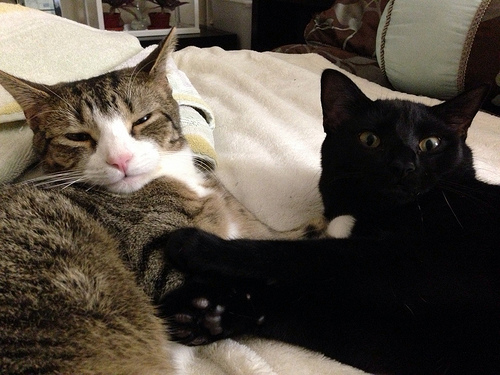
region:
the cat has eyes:
[348, 115, 445, 165]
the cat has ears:
[305, 51, 486, 130]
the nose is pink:
[97, 147, 142, 174]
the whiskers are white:
[37, 168, 92, 192]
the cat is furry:
[20, 240, 110, 320]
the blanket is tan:
[222, 67, 289, 173]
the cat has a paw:
[160, 294, 238, 346]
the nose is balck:
[388, 154, 418, 186]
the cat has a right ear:
[138, 20, 193, 76]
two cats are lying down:
[11, 42, 493, 358]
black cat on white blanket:
[140, 68, 497, 367]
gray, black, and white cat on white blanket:
[4, 29, 352, 371]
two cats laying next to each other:
[2, 27, 497, 370]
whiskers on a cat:
[15, 147, 221, 187]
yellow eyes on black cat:
[355, 125, 440, 155]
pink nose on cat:
[99, 146, 139, 174]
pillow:
[373, 1, 491, 101]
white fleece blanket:
[157, 43, 499, 373]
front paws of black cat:
[138, 225, 242, 357]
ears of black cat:
[313, 63, 486, 139]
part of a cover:
[266, 148, 278, 160]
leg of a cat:
[240, 274, 247, 288]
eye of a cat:
[368, 124, 378, 153]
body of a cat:
[101, 324, 121, 344]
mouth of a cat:
[124, 157, 127, 179]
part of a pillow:
[391, 60, 401, 80]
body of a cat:
[370, 230, 397, 275]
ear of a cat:
[150, 65, 157, 75]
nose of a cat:
[124, 156, 158, 181]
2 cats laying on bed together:
[4, 51, 492, 373]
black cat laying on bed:
[213, 65, 498, 372]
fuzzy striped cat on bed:
[0, 50, 235, 372]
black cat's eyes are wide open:
[306, 60, 498, 210]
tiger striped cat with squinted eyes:
[3, 41, 195, 202]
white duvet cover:
[6, 2, 491, 149]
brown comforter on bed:
[291, 1, 498, 96]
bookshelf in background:
[86, 4, 206, 44]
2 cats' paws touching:
[121, 177, 358, 362]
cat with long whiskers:
[0, 62, 239, 214]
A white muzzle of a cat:
[89, 132, 161, 192]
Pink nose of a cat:
[107, 146, 140, 181]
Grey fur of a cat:
[45, 297, 122, 359]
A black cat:
[221, 83, 496, 333]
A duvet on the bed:
[237, 84, 314, 210]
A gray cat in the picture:
[0, 64, 237, 372]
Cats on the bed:
[5, 53, 497, 373]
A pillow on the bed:
[0, 13, 116, 71]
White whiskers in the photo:
[55, 166, 95, 190]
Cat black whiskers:
[391, 173, 470, 235]